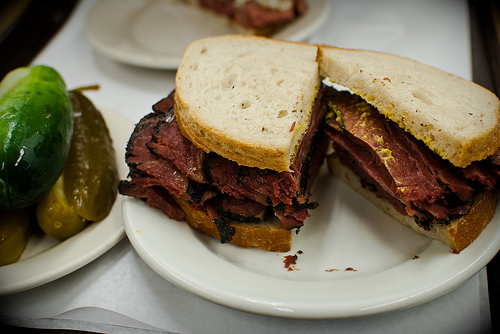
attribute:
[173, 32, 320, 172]
bread — slice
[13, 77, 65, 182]
pickle — green 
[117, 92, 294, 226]
meat — burnt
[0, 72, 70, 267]
pickle — green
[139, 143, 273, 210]
meat — smoked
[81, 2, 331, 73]
plate — half-empty, white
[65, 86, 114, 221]
pickle — dark green 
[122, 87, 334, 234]
meat — smoked